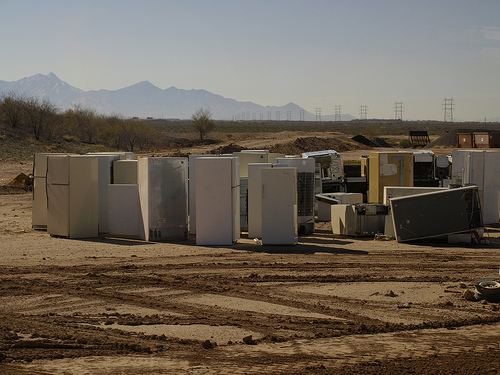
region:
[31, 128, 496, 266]
fridges in a junk yard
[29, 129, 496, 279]
broken refrigerators in a yard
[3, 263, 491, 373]
there are many tire tracks in the dirt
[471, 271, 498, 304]
an old wheel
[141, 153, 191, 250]
the silver back of a refrigerator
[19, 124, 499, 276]
old kitchen appliances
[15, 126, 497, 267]
a collection of broken fridges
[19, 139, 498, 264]
old and broken refrigerators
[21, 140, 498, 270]
a collection of obsolete refrigerators on dirt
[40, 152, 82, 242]
the front of a refrigerator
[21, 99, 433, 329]
Refrigerators on the dirt.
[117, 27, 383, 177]
Mountains in the background.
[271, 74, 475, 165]
Power poles in the background.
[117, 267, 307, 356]
Dirt on the ground.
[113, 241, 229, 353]
Clumps of dirt on the ground.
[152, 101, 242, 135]
Trees in the background.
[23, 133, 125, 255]
White refrigerator on the dirt.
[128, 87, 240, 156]
Green tree in the background.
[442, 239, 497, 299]
Tire on the ground.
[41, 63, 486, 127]
Mountains behind the refrigerators.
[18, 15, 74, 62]
white clouds in blue sky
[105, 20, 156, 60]
white clouds in blue sky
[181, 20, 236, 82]
white clouds in blue sky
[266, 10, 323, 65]
white clouds in blue sky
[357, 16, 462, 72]
white clouds in blue sky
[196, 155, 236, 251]
old white refrigerator outside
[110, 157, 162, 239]
old white refrigerator outside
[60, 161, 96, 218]
old white refrigerator outside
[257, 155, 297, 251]
old white refrigerator outside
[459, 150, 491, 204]
old white refrigerator outside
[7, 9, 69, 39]
white clouds in blue sky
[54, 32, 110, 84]
white clouds in blue sky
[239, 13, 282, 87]
white clouds in blue sky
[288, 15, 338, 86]
white clouds in blue sky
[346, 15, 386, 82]
white clouds in blue sky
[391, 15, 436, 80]
white clouds in blue sky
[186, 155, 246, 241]
old white refrigerator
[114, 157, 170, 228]
old white refrigerator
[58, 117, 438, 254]
Refrigerators in the dirt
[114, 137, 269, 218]
Refrigerators in the dirt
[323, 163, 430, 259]
Refrigerators in the dirt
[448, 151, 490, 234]
Refrigerators in the dirt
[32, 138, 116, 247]
Refrigerators in the dirt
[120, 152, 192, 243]
Refrigerators in the dirt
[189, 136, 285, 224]
Refrigerators in the dirt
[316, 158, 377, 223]
Refrigerators in the dirt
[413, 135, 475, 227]
Refrigerators in the dirt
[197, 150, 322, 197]
Refrigerators in the dirt